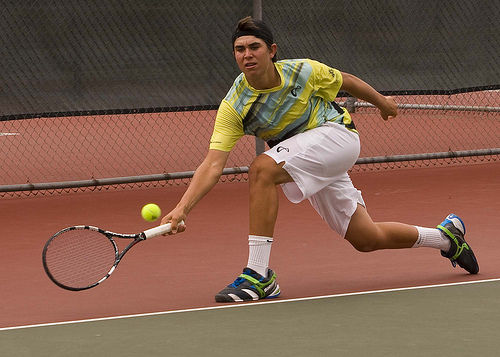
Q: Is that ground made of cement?
A: Yes, the ground is made of cement.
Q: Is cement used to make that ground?
A: Yes, the ground is made of cement.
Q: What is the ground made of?
A: The ground is made of concrete.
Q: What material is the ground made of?
A: The ground is made of concrete.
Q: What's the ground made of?
A: The ground is made of concrete.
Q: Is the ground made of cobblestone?
A: No, the ground is made of concrete.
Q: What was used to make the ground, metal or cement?
A: The ground is made of cement.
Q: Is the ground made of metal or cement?
A: The ground is made of cement.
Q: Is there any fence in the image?
A: Yes, there is a fence.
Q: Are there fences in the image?
A: Yes, there is a fence.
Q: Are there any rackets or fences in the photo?
A: Yes, there is a fence.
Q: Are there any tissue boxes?
A: No, there are no tissue boxes.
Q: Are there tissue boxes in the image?
A: No, there are no tissue boxes.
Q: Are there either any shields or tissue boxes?
A: No, there are no tissue boxes or shields.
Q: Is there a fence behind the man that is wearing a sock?
A: Yes, there is a fence behind the man.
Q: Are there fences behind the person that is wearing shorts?
A: Yes, there is a fence behind the man.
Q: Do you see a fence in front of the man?
A: No, the fence is behind the man.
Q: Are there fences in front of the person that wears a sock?
A: No, the fence is behind the man.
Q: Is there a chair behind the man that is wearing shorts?
A: No, there is a fence behind the man.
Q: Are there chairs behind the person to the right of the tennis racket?
A: No, there is a fence behind the man.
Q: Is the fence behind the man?
A: Yes, the fence is behind the man.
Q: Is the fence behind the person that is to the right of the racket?
A: Yes, the fence is behind the man.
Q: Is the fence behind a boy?
A: No, the fence is behind the man.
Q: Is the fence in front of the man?
A: No, the fence is behind the man.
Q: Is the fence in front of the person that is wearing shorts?
A: No, the fence is behind the man.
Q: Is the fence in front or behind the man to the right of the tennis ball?
A: The fence is behind the man.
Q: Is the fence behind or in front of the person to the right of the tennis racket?
A: The fence is behind the man.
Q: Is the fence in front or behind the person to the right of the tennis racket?
A: The fence is behind the man.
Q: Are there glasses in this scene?
A: No, there are no glasses.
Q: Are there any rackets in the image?
A: Yes, there is a racket.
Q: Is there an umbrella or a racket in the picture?
A: Yes, there is a racket.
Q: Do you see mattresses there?
A: No, there are no mattresses.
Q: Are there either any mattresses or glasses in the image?
A: No, there are no mattresses or glasses.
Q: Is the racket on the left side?
A: Yes, the racket is on the left of the image.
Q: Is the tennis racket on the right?
A: No, the tennis racket is on the left of the image.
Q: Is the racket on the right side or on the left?
A: The racket is on the left of the image.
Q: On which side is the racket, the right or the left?
A: The racket is on the left of the image.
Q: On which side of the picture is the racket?
A: The racket is on the left of the image.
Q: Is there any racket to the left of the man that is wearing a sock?
A: Yes, there is a racket to the left of the man.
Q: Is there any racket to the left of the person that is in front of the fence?
A: Yes, there is a racket to the left of the man.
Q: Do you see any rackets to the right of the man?
A: No, the racket is to the left of the man.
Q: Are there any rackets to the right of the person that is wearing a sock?
A: No, the racket is to the left of the man.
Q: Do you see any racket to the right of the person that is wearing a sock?
A: No, the racket is to the left of the man.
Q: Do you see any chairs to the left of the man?
A: No, there is a racket to the left of the man.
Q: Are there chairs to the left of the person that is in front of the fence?
A: No, there is a racket to the left of the man.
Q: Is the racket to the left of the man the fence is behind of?
A: Yes, the racket is to the left of the man.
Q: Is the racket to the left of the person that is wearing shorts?
A: Yes, the racket is to the left of the man.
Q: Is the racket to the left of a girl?
A: No, the racket is to the left of the man.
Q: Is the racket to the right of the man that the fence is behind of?
A: No, the racket is to the left of the man.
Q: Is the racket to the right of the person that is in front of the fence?
A: No, the racket is to the left of the man.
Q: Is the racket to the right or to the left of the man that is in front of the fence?
A: The racket is to the left of the man.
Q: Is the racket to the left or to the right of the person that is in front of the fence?
A: The racket is to the left of the man.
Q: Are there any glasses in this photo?
A: No, there are no glasses.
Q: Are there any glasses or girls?
A: No, there are no glasses or girls.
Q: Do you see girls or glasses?
A: No, there are no glasses or girls.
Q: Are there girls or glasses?
A: No, there are no glasses or girls.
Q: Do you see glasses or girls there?
A: No, there are no glasses or girls.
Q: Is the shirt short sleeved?
A: Yes, the shirt is short sleeved.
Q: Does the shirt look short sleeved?
A: Yes, the shirt is short sleeved.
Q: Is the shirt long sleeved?
A: No, the shirt is short sleeved.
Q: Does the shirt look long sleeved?
A: No, the shirt is short sleeved.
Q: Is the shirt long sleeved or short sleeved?
A: The shirt is short sleeved.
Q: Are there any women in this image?
A: No, there are no women.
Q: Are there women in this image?
A: No, there are no women.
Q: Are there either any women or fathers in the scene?
A: No, there are no women or fathers.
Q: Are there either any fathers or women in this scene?
A: No, there are no women or fathers.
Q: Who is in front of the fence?
A: The man is in front of the fence.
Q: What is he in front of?
A: The man is in front of the fence.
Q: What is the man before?
A: The man is in front of the fence.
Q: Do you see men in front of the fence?
A: Yes, there is a man in front of the fence.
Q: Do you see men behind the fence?
A: No, the man is in front of the fence.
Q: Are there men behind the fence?
A: No, the man is in front of the fence.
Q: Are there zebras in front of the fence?
A: No, there is a man in front of the fence.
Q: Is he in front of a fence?
A: Yes, the man is in front of a fence.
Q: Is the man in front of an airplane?
A: No, the man is in front of a fence.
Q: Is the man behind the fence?
A: No, the man is in front of the fence.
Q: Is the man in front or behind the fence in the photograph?
A: The man is in front of the fence.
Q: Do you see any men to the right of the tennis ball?
A: Yes, there is a man to the right of the tennis ball.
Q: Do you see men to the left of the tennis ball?
A: No, the man is to the right of the tennis ball.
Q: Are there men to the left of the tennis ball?
A: No, the man is to the right of the tennis ball.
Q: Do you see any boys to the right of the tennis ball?
A: No, there is a man to the right of the tennis ball.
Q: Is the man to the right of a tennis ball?
A: Yes, the man is to the right of a tennis ball.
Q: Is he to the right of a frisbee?
A: No, the man is to the right of a tennis ball.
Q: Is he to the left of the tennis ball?
A: No, the man is to the right of the tennis ball.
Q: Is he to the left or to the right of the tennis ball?
A: The man is to the right of the tennis ball.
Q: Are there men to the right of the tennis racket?
A: Yes, there is a man to the right of the tennis racket.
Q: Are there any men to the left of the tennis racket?
A: No, the man is to the right of the tennis racket.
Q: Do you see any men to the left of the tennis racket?
A: No, the man is to the right of the tennis racket.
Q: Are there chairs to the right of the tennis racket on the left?
A: No, there is a man to the right of the racket.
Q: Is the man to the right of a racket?
A: Yes, the man is to the right of a racket.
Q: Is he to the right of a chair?
A: No, the man is to the right of a racket.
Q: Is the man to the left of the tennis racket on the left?
A: No, the man is to the right of the racket.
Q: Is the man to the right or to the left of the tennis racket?
A: The man is to the right of the tennis racket.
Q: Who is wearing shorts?
A: The man is wearing shorts.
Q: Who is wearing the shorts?
A: The man is wearing shorts.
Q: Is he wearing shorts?
A: Yes, the man is wearing shorts.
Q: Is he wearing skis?
A: No, the man is wearing shorts.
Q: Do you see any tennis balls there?
A: Yes, there is a tennis ball.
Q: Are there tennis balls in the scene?
A: Yes, there is a tennis ball.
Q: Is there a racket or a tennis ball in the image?
A: Yes, there is a tennis ball.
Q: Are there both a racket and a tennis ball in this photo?
A: Yes, there are both a tennis ball and a racket.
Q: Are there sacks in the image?
A: No, there are no sacks.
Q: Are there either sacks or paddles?
A: No, there are no sacks or paddles.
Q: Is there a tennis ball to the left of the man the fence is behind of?
A: Yes, there is a tennis ball to the left of the man.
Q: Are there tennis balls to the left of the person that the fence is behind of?
A: Yes, there is a tennis ball to the left of the man.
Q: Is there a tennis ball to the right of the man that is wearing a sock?
A: No, the tennis ball is to the left of the man.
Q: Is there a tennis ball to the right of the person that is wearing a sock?
A: No, the tennis ball is to the left of the man.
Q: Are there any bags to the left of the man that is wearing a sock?
A: No, there is a tennis ball to the left of the man.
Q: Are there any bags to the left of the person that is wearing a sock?
A: No, there is a tennis ball to the left of the man.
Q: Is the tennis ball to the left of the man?
A: Yes, the tennis ball is to the left of the man.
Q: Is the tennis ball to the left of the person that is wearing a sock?
A: Yes, the tennis ball is to the left of the man.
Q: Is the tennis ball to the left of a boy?
A: No, the tennis ball is to the left of the man.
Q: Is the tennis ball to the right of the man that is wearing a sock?
A: No, the tennis ball is to the left of the man.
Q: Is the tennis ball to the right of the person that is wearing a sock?
A: No, the tennis ball is to the left of the man.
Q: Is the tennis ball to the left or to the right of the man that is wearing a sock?
A: The tennis ball is to the left of the man.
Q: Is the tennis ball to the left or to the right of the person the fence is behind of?
A: The tennis ball is to the left of the man.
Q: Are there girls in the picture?
A: No, there are no girls.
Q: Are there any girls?
A: No, there are no girls.